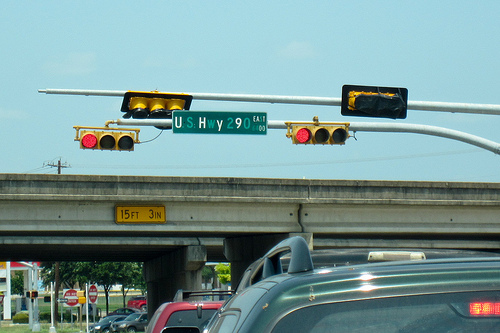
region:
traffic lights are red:
[68, 120, 381, 157]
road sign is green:
[174, 109, 266, 136]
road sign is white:
[174, 111, 271, 134]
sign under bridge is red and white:
[56, 277, 105, 312]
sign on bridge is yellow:
[121, 200, 173, 230]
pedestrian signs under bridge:
[20, 281, 53, 307]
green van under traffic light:
[230, 257, 498, 328]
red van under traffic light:
[156, 278, 259, 330]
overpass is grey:
[13, 169, 496, 247]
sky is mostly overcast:
[25, 6, 485, 155]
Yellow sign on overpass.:
[106, 190, 226, 251]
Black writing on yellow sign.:
[106, 186, 190, 230]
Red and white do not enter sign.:
[78, 276, 124, 317]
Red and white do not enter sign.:
[61, 277, 84, 308]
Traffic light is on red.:
[84, 135, 127, 180]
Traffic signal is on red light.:
[286, 120, 333, 165]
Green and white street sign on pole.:
[168, 93, 337, 178]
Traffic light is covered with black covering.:
[343, 79, 425, 157]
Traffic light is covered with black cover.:
[129, 90, 181, 129]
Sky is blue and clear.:
[37, 71, 273, 178]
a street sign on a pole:
[146, 81, 276, 164]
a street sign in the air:
[161, 87, 291, 177]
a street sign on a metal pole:
[147, 93, 297, 162]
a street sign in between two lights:
[65, 92, 383, 207]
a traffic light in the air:
[60, 99, 178, 171]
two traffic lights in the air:
[64, 95, 379, 180]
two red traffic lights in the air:
[49, 77, 372, 180]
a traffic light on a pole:
[35, 98, 162, 153]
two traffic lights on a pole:
[67, 96, 392, 196]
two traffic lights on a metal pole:
[48, 77, 388, 231]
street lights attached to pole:
[33, 54, 428, 202]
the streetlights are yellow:
[65, 116, 378, 171]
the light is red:
[73, 122, 116, 175]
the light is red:
[293, 125, 318, 151]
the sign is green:
[166, 94, 277, 143]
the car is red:
[143, 279, 235, 331]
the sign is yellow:
[99, 194, 174, 233]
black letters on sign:
[112, 199, 174, 230]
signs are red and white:
[44, 276, 121, 324]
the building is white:
[5, 260, 40, 305]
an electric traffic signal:
[69, 124, 141, 154]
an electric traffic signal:
[286, 118, 351, 146]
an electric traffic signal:
[338, 82, 407, 115]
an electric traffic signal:
[111, 89, 192, 121]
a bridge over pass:
[3, 168, 495, 309]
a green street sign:
[166, 106, 268, 138]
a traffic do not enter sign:
[60, 286, 81, 319]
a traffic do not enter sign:
[85, 283, 100, 316]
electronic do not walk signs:
[20, 286, 42, 323]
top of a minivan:
[205, 235, 497, 328]